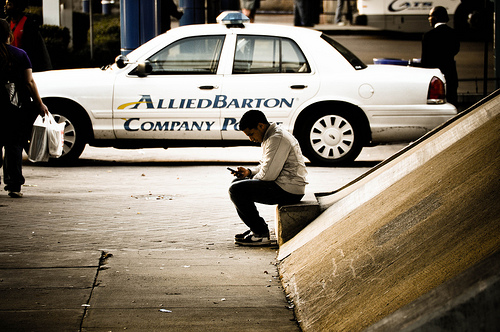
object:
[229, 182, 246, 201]
knees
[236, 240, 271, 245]
sole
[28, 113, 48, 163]
bag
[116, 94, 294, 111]
writing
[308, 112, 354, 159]
rims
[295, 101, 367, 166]
tire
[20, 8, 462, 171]
car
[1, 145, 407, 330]
ground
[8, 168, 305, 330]
path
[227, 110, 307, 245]
man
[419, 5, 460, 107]
man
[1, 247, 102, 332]
stone ground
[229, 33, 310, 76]
window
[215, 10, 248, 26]
lights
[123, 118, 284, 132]
writings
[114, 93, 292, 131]
logo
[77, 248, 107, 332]
line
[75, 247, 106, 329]
part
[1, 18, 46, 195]
man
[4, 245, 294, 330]
floor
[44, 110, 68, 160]
bag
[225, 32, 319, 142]
door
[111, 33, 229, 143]
door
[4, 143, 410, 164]
road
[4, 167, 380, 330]
sidewalk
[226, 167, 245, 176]
phone